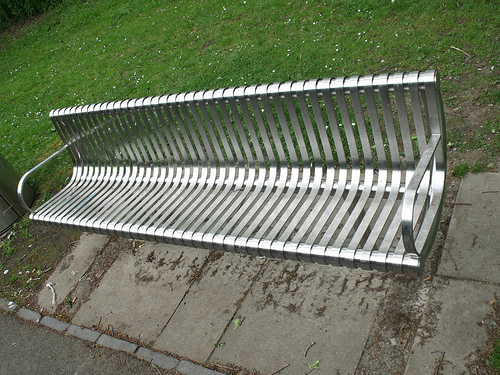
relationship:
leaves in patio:
[9, 227, 491, 374] [10, 25, 488, 369]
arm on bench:
[399, 131, 447, 259] [15, 80, 455, 291]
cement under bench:
[25, 239, 367, 370] [15, 80, 455, 291]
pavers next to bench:
[33, 230, 433, 372] [15, 80, 455, 291]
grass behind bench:
[5, 4, 498, 69] [15, 80, 455, 291]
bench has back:
[15, 80, 455, 291] [43, 57, 461, 182]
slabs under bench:
[55, 182, 499, 367] [15, 80, 455, 291]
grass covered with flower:
[5, 4, 498, 69] [378, 59, 386, 64]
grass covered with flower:
[5, 4, 498, 69] [392, 31, 400, 38]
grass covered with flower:
[5, 4, 498, 69] [311, 20, 317, 25]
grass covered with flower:
[5, 4, 498, 69] [270, 67, 276, 74]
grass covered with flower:
[5, 4, 498, 69] [195, 33, 200, 40]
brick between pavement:
[135, 345, 179, 373] [0, 304, 170, 373]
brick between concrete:
[135, 345, 179, 373] [41, 166, 484, 365]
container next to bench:
[0, 142, 32, 238] [15, 80, 455, 291]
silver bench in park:
[14, 69, 449, 279] [0, 0, 498, 374]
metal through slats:
[111, 173, 430, 280] [18, 65, 449, 275]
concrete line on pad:
[41, 238, 117, 313] [22, 152, 484, 372]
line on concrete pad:
[354, 310, 379, 341] [35, 169, 497, 369]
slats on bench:
[26, 57, 460, 297] [15, 80, 455, 291]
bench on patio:
[15, 80, 455, 291] [27, 168, 496, 368]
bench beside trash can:
[15, 80, 455, 291] [0, 153, 35, 240]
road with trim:
[4, 301, 181, 367] [10, 291, 175, 357]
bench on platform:
[15, 80, 455, 291] [63, 170, 495, 368]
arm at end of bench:
[399, 131, 447, 259] [7, 62, 465, 289]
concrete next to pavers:
[20, 327, 231, 364] [0, 12, 499, 370]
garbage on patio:
[38, 281, 60, 308] [2, 1, 496, 371]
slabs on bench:
[55, 182, 499, 367] [15, 80, 455, 291]